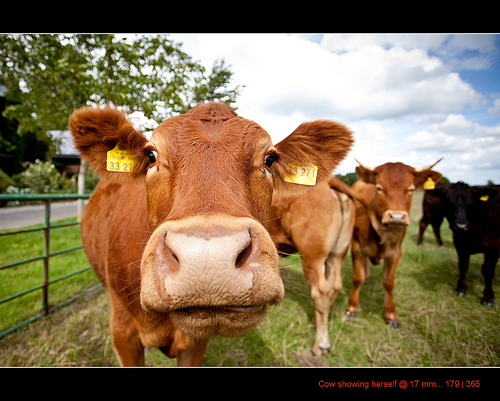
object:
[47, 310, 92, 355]
grass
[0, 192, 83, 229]
street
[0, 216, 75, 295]
grass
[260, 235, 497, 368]
grass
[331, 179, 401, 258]
tail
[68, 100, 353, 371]
cow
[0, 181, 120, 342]
fence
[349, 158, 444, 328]
cow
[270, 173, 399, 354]
cow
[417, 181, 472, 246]
cow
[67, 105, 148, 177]
ear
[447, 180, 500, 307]
black cow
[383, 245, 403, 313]
front legs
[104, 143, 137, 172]
tag